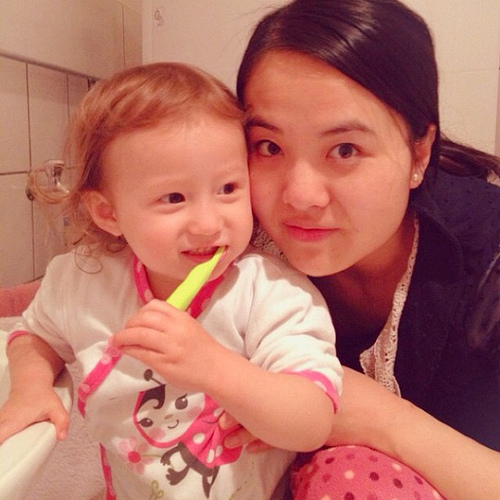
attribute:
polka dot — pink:
[330, 454, 383, 499]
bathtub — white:
[3, 441, 53, 477]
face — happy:
[109, 109, 254, 282]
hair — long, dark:
[235, 1, 499, 175]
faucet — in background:
[31, 155, 71, 207]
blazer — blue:
[389, 170, 496, 453]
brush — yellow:
[163, 247, 225, 310]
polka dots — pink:
[390, 461, 403, 472]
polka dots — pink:
[342, 470, 354, 478]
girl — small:
[8, 58, 438, 498]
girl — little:
[3, 63, 339, 497]